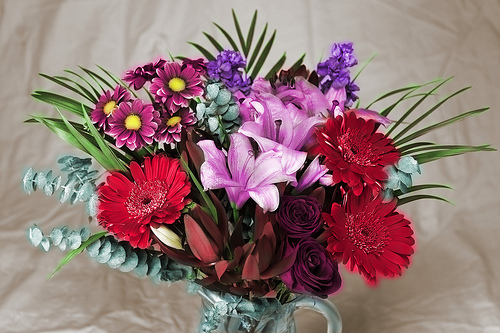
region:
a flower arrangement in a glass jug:
[12, 10, 497, 331]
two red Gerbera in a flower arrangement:
[309, 108, 418, 289]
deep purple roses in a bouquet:
[269, 188, 343, 301]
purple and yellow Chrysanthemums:
[85, 53, 206, 153]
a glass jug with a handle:
[186, 280, 349, 332]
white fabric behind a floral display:
[4, 38, 499, 329]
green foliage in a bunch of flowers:
[21, 55, 213, 222]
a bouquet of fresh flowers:
[15, 6, 495, 303]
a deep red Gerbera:
[91, 148, 194, 253]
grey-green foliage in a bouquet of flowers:
[27, 223, 194, 290]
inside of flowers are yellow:
[101, 68, 192, 146]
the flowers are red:
[316, 105, 435, 295]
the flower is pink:
[189, 128, 321, 228]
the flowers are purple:
[86, 56, 207, 153]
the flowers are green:
[14, 152, 193, 294]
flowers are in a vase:
[0, 0, 480, 331]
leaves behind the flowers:
[359, 70, 490, 227]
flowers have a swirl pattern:
[282, 197, 343, 299]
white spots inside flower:
[124, 185, 173, 212]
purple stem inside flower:
[267, 109, 288, 147]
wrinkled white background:
[20, 27, 495, 328]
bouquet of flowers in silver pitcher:
[20, 16, 410, 326]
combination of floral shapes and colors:
[20, 6, 495, 326]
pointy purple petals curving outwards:
[195, 125, 285, 210]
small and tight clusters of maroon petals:
[275, 195, 335, 290]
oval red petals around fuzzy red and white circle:
[95, 155, 190, 245]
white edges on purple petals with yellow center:
[106, 96, 156, 146]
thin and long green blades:
[375, 71, 490, 153]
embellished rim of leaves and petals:
[187, 281, 297, 326]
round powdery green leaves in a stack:
[26, 217, 167, 277]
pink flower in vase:
[324, 193, 415, 283]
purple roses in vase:
[281, 201, 343, 296]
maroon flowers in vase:
[185, 209, 295, 294]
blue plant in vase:
[28, 228, 183, 290]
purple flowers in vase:
[206, 50, 248, 91]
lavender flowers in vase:
[198, 79, 382, 209]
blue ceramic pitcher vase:
[195, 289, 342, 331]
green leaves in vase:
[21, 64, 131, 176]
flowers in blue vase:
[13, 11, 493, 301]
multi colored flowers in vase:
[11, 10, 486, 302]